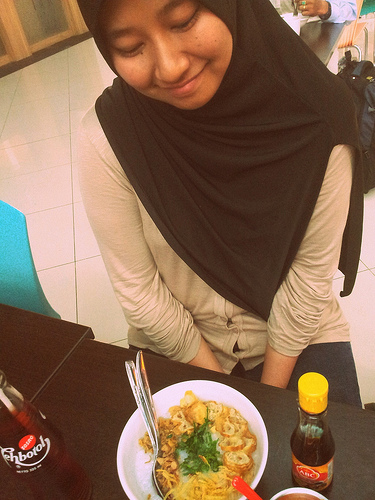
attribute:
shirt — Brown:
[69, 85, 356, 379]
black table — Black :
[0, 304, 371, 497]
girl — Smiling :
[72, 1, 365, 411]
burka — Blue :
[72, 0, 362, 320]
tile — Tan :
[338, 282, 373, 339]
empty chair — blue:
[1, 191, 64, 317]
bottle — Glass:
[289, 351, 349, 491]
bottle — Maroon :
[264, 356, 345, 499]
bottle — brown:
[287, 369, 336, 493]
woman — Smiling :
[53, 7, 373, 368]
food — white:
[138, 376, 288, 497]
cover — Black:
[79, 0, 374, 328]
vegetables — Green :
[137, 387, 277, 496]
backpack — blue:
[329, 51, 373, 192]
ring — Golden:
[302, 3, 307, 10]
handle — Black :
[351, 58, 372, 78]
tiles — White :
[9, 39, 135, 300]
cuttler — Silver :
[130, 346, 166, 498]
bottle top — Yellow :
[293, 366, 341, 416]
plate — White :
[112, 376, 272, 498]